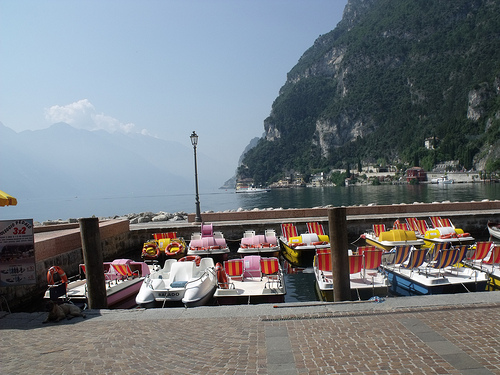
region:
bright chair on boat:
[108, 260, 138, 283]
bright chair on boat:
[221, 253, 241, 278]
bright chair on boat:
[256, 253, 280, 277]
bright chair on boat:
[312, 243, 344, 278]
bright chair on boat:
[340, 253, 360, 273]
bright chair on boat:
[354, 246, 386, 272]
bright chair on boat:
[405, 244, 425, 274]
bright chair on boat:
[434, 248, 451, 268]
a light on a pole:
[187, 128, 212, 218]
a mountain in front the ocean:
[217, 0, 498, 202]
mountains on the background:
[0, 107, 220, 198]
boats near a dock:
[35, 205, 495, 305]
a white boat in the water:
[222, 175, 267, 197]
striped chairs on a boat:
[255, 251, 280, 281]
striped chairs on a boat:
[210, 245, 285, 300]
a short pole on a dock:
[323, 195, 356, 303]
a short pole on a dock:
[73, 213, 116, 317]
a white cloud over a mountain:
[9, 90, 214, 193]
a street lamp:
[188, 133, 203, 222]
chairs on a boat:
[209, 254, 281, 275]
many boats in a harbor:
[92, 230, 497, 307]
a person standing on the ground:
[46, 268, 83, 310]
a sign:
[1, 215, 43, 296]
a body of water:
[53, 176, 433, 212]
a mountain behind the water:
[237, 45, 473, 177]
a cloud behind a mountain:
[50, 96, 114, 126]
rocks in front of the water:
[117, 214, 177, 220]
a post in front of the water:
[326, 202, 352, 299]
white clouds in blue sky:
[23, 18, 83, 75]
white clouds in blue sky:
[134, 20, 176, 55]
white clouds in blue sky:
[180, 5, 238, 59]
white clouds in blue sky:
[102, 34, 169, 97]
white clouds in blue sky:
[103, 147, 142, 186]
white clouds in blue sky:
[43, 78, 68, 122]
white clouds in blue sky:
[80, 26, 155, 86]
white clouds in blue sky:
[58, 10, 134, 77]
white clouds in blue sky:
[191, 33, 236, 81]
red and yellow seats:
[227, 268, 284, 278]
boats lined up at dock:
[151, 218, 474, 297]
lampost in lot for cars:
[186, 129, 200, 216]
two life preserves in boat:
[139, 241, 190, 256]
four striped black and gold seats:
[390, 241, 467, 268]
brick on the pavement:
[1, 332, 498, 374]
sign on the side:
[0, 225, 46, 291]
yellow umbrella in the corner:
[0, 189, 25, 214]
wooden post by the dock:
[328, 209, 364, 299]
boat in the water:
[220, 183, 284, 206]